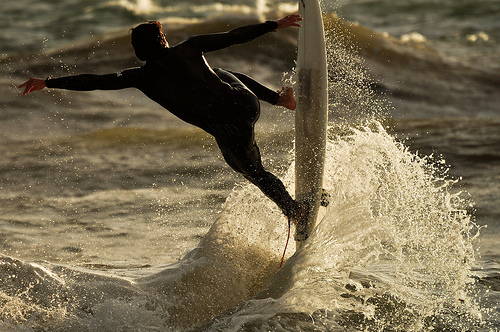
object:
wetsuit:
[52, 18, 295, 219]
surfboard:
[292, 0, 330, 253]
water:
[83, 218, 223, 274]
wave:
[223, 210, 385, 325]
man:
[18, 11, 309, 237]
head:
[130, 19, 171, 61]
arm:
[50, 71, 115, 97]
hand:
[17, 75, 50, 96]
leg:
[227, 137, 303, 231]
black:
[190, 87, 234, 119]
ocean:
[0, 0, 499, 332]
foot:
[267, 85, 297, 111]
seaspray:
[331, 88, 444, 243]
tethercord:
[270, 201, 304, 272]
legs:
[228, 65, 299, 116]